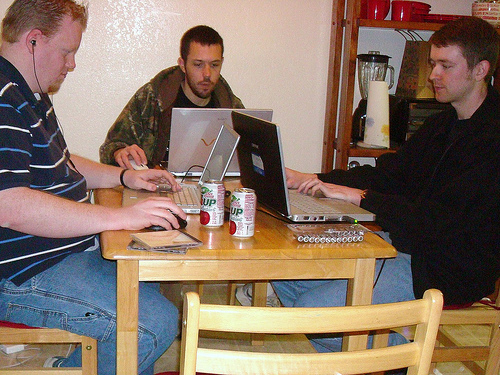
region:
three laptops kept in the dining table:
[143, 101, 350, 243]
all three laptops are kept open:
[161, 102, 346, 234]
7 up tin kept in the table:
[198, 174, 258, 230]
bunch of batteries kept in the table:
[297, 229, 377, 251]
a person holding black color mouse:
[137, 193, 189, 232]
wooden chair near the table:
[176, 296, 453, 373]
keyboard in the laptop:
[293, 189, 330, 219]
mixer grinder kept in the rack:
[347, 30, 406, 150]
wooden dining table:
[98, 159, 384, 287]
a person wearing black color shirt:
[393, 115, 491, 295]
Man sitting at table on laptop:
[247, 38, 489, 350]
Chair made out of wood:
[180, 267, 405, 366]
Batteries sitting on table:
[288, 220, 385, 284]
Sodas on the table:
[197, 156, 263, 248]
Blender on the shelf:
[358, 45, 395, 155]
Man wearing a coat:
[107, 35, 222, 180]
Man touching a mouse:
[118, 193, 203, 261]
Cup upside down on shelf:
[357, 70, 395, 172]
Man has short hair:
[410, 15, 499, 134]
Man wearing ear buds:
[25, 22, 73, 115]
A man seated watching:
[372, 34, 498, 256]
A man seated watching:
[117, 7, 239, 160]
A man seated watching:
[6, 1, 122, 274]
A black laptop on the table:
[240, 109, 367, 231]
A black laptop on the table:
[157, 134, 246, 197]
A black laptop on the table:
[163, 116, 293, 193]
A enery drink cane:
[227, 184, 269, 253]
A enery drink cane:
[201, 189, 225, 234]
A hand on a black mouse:
[131, 216, 186, 231]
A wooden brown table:
[208, 234, 298, 265]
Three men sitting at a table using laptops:
[2, 0, 498, 368]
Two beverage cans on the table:
[198, 181, 258, 238]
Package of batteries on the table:
[293, 224, 366, 245]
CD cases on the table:
[129, 226, 202, 253]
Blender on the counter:
[352, 51, 398, 139]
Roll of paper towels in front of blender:
[364, 80, 392, 145]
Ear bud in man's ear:
[25, 24, 39, 56]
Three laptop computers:
[120, 104, 377, 227]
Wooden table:
[94, 170, 398, 373]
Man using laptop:
[232, 15, 498, 314]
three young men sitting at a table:
[0, 1, 460, 282]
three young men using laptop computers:
[32, 27, 497, 244]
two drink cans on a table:
[185, 169, 262, 246]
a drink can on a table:
[224, 178, 265, 247]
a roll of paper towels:
[352, 74, 396, 163]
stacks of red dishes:
[353, 2, 439, 29]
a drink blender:
[340, 34, 395, 154]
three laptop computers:
[165, 92, 286, 193]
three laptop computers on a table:
[145, 101, 286, 253]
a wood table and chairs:
[70, 145, 387, 372]